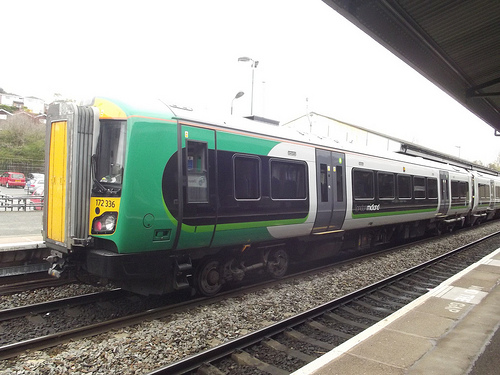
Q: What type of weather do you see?
A: It is cloudy.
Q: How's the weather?
A: It is cloudy.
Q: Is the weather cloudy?
A: Yes, it is cloudy.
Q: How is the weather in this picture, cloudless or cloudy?
A: It is cloudy.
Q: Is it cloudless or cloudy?
A: It is cloudy.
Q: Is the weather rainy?
A: No, it is cloudy.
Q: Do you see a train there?
A: Yes, there is a train.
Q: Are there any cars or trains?
A: Yes, there is a train.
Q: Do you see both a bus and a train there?
A: No, there is a train but no buses.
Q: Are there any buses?
A: No, there are no buses.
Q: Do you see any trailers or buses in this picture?
A: No, there are no buses or trailers.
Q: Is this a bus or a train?
A: This is a train.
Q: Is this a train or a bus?
A: This is a train.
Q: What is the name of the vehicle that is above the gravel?
A: The vehicle is a train.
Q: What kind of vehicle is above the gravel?
A: The vehicle is a train.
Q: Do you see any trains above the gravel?
A: Yes, there is a train above the gravel.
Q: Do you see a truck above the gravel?
A: No, there is a train above the gravel.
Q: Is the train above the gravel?
A: Yes, the train is above the gravel.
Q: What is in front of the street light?
A: The train is in front of the street light.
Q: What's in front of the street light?
A: The train is in front of the street light.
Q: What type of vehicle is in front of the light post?
A: The vehicle is a train.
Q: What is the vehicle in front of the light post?
A: The vehicle is a train.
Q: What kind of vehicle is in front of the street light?
A: The vehicle is a train.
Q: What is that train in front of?
A: The train is in front of the street light.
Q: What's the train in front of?
A: The train is in front of the street light.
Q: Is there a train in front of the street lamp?
A: Yes, there is a train in front of the street lamp.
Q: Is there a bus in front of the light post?
A: No, there is a train in front of the light post.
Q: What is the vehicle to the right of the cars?
A: The vehicle is a train.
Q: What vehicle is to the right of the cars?
A: The vehicle is a train.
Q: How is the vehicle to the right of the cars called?
A: The vehicle is a train.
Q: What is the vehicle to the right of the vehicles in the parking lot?
A: The vehicle is a train.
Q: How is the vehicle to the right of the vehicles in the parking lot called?
A: The vehicle is a train.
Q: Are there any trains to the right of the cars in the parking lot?
A: Yes, there is a train to the right of the cars.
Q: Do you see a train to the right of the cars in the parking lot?
A: Yes, there is a train to the right of the cars.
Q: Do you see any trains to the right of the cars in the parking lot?
A: Yes, there is a train to the right of the cars.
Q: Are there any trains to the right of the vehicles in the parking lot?
A: Yes, there is a train to the right of the cars.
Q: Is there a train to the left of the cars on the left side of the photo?
A: No, the train is to the right of the cars.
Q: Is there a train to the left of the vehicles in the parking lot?
A: No, the train is to the right of the cars.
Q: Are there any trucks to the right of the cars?
A: No, there is a train to the right of the cars.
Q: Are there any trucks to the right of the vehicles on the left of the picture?
A: No, there is a train to the right of the cars.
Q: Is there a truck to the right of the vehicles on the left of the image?
A: No, there is a train to the right of the cars.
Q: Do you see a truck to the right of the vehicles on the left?
A: No, there is a train to the right of the cars.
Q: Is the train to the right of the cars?
A: Yes, the train is to the right of the cars.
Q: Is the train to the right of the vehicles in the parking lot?
A: Yes, the train is to the right of the cars.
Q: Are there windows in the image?
A: Yes, there are windows.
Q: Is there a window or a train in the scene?
A: Yes, there are windows.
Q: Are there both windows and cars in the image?
A: Yes, there are both windows and a car.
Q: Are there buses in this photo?
A: No, there are no buses.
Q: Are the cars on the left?
A: Yes, the cars are on the left of the image.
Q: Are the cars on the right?
A: No, the cars are on the left of the image.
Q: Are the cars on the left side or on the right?
A: The cars are on the left of the image.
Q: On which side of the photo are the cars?
A: The cars are on the left of the image.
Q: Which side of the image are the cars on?
A: The cars are on the left of the image.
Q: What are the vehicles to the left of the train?
A: The vehicles are cars.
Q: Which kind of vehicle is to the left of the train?
A: The vehicles are cars.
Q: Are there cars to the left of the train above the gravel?
A: Yes, there are cars to the left of the train.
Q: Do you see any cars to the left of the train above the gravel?
A: Yes, there are cars to the left of the train.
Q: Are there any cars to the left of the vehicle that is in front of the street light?
A: Yes, there are cars to the left of the train.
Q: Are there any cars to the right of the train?
A: No, the cars are to the left of the train.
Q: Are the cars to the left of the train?
A: Yes, the cars are to the left of the train.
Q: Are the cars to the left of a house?
A: No, the cars are to the left of the train.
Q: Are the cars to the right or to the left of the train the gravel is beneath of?
A: The cars are to the left of the train.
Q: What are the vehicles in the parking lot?
A: The vehicles are cars.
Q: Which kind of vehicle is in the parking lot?
A: The vehicles are cars.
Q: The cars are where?
A: The cars are in the parking lot.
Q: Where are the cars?
A: The cars are in the parking lot.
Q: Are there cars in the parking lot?
A: Yes, there are cars in the parking lot.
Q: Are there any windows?
A: Yes, there are windows.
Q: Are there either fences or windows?
A: Yes, there are windows.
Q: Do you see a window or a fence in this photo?
A: Yes, there are windows.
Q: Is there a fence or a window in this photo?
A: Yes, there are windows.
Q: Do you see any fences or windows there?
A: Yes, there are windows.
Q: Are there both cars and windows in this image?
A: Yes, there are both windows and a car.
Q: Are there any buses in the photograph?
A: No, there are no buses.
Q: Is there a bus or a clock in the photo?
A: No, there are no buses or clocks.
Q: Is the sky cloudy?
A: Yes, the sky is cloudy.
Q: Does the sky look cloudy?
A: Yes, the sky is cloudy.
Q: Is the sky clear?
A: No, the sky is cloudy.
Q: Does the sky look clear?
A: No, the sky is cloudy.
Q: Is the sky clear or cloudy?
A: The sky is cloudy.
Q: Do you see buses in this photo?
A: No, there are no buses.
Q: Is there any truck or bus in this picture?
A: No, there are no buses or trucks.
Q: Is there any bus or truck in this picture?
A: No, there are no buses or trucks.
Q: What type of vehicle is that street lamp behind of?
A: The street lamp is behind the train.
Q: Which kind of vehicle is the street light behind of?
A: The street lamp is behind the train.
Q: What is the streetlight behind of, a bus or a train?
A: The streetlight is behind a train.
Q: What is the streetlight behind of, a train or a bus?
A: The streetlight is behind a train.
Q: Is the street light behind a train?
A: Yes, the street light is behind a train.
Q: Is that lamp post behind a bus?
A: No, the lamp post is behind a train.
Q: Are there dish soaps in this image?
A: No, there are no dish soaps.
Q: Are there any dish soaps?
A: No, there are no dish soaps.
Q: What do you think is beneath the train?
A: The gravel is beneath the train.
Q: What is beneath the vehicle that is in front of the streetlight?
A: The gravel is beneath the train.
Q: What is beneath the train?
A: The gravel is beneath the train.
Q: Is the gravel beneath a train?
A: Yes, the gravel is beneath a train.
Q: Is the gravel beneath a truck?
A: No, the gravel is beneath a train.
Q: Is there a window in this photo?
A: Yes, there are windows.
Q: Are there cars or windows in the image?
A: Yes, there are windows.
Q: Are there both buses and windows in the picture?
A: No, there are windows but no buses.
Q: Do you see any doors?
A: Yes, there are doors.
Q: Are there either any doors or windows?
A: Yes, there are doors.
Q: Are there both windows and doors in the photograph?
A: Yes, there are both doors and a window.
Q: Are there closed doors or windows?
A: Yes, there are closed doors.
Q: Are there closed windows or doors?
A: Yes, there are closed doors.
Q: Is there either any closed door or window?
A: Yes, there are closed doors.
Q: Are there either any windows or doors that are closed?
A: Yes, the doors are closed.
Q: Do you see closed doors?
A: Yes, there are closed doors.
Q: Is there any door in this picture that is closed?
A: Yes, there are doors that are closed.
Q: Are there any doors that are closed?
A: Yes, there are doors that are closed.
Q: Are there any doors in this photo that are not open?
A: Yes, there are closed doors.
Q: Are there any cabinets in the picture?
A: No, there are no cabinets.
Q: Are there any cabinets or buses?
A: No, there are no cabinets or buses.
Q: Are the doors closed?
A: Yes, the doors are closed.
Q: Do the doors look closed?
A: Yes, the doors are closed.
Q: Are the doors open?
A: No, the doors are closed.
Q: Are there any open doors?
A: No, there are doors but they are closed.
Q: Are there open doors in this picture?
A: No, there are doors but they are closed.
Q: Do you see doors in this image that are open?
A: No, there are doors but they are closed.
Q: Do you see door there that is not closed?
A: No, there are doors but they are closed.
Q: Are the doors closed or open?
A: The doors are closed.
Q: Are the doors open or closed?
A: The doors are closed.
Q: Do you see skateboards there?
A: No, there are no skateboards.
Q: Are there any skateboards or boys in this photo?
A: No, there are no skateboards or boys.